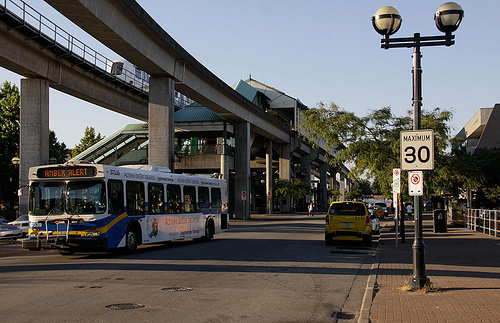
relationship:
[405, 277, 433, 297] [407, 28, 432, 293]
grass growing around post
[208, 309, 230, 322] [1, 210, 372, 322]
stain on road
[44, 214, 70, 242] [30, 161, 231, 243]
bike rack on front of bus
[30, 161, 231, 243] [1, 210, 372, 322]
bus on road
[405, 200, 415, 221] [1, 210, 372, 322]
man walking on road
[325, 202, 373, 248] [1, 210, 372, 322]
cab on top of road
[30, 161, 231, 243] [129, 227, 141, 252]
bus has wheel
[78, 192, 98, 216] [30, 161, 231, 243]
driver inside bus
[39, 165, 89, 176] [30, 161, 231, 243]
letters on front of bus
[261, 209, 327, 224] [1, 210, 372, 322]
shadow on top of road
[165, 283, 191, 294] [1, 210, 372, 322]
man hole on road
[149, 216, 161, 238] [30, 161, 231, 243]
logo on side of bus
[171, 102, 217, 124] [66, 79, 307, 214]
roof on building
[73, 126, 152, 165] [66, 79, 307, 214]
steps leading up to building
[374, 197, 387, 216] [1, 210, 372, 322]
van on road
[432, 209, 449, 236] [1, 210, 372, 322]
trash can on road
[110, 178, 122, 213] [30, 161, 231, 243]
window on side of bus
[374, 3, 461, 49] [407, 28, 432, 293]
light attached to post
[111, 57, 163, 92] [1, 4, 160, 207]
train on top of bridge